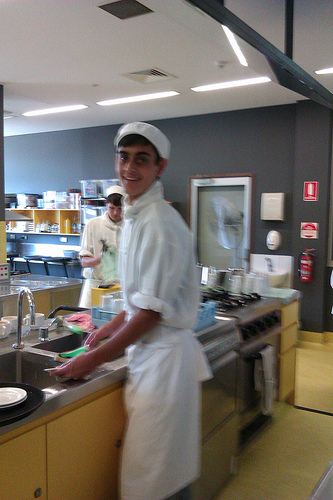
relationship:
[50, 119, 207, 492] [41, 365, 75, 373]
man washing dishes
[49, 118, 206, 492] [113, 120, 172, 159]
boy wearing a hat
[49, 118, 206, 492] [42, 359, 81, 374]
boy washing dishes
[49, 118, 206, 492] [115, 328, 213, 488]
boy wearing an apron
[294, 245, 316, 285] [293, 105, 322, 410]
fire extinguisher hanging on wall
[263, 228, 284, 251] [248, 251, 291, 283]
dispenser above sink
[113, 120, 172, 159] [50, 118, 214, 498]
hat worn by man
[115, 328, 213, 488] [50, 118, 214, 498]
apron worn by man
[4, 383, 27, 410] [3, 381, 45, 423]
plates sit on tray